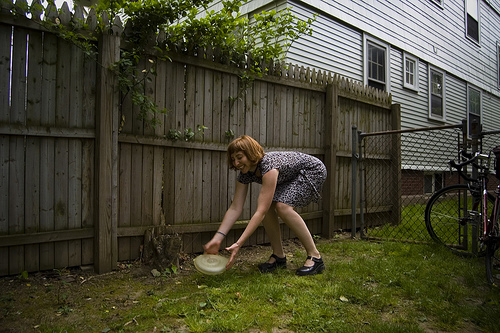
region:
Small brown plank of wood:
[5, 243, 30, 282]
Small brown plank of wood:
[17, 242, 49, 264]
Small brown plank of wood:
[46, 240, 83, 275]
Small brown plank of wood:
[81, 229, 102, 273]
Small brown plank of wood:
[115, 233, 140, 260]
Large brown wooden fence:
[5, 1, 407, 253]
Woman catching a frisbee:
[172, 100, 342, 285]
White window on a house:
[359, 33, 390, 99]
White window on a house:
[397, 43, 421, 98]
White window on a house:
[424, 58, 451, 126]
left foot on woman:
[287, 251, 335, 274]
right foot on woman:
[262, 247, 288, 271]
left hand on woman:
[221, 246, 245, 261]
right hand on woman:
[201, 239, 227, 258]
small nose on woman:
[229, 157, 244, 168]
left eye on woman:
[238, 147, 243, 157]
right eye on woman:
[229, 152, 234, 162]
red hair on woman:
[239, 137, 272, 169]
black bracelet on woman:
[204, 224, 234, 241]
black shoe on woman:
[300, 253, 327, 283]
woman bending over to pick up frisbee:
[196, 133, 334, 278]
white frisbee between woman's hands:
[193, 248, 231, 277]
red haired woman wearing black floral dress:
[190, 128, 340, 285]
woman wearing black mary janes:
[193, 132, 337, 284]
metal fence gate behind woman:
[343, 101, 498, 246]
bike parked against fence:
[411, 126, 497, 267]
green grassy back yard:
[8, 213, 488, 324]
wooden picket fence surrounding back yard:
[4, 2, 407, 260]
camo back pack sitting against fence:
[142, 220, 189, 278]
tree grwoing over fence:
[70, 0, 323, 132]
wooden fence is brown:
[0, 0, 404, 277]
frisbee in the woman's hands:
[192, 253, 229, 272]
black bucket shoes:
[257, 252, 323, 274]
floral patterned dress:
[235, 150, 325, 205]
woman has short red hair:
[224, 135, 263, 170]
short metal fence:
[352, 124, 499, 246]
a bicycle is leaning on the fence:
[425, 145, 499, 255]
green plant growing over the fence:
[37, 0, 300, 131]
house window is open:
[358, 38, 388, 94]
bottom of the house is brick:
[393, 168, 476, 200]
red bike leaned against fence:
[425, 138, 495, 260]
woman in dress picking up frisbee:
[192, 135, 324, 280]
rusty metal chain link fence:
[349, 126, 476, 248]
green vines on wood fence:
[115, 30, 173, 137]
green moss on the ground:
[128, 296, 186, 326]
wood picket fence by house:
[334, 75, 399, 229]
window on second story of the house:
[464, 0, 479, 45]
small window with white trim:
[404, 54, 419, 91]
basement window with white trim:
[419, 169, 445, 195]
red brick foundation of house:
[399, 171, 421, 208]